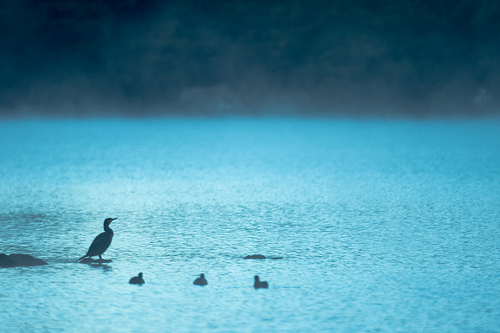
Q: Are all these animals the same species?
A: Yes, all the animals are ducks.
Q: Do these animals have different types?
A: No, all the animals are ducks.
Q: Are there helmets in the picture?
A: No, there are no helmets.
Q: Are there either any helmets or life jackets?
A: No, there are no helmets or life jackets.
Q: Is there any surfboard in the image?
A: No, there are no surfboards.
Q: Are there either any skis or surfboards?
A: No, there are no surfboards or skis.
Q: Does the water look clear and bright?
A: Yes, the water is clear and bright.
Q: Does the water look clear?
A: Yes, the water is clear.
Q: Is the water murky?
A: No, the water is clear.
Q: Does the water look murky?
A: No, the water is clear.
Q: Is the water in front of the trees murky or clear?
A: The water is clear.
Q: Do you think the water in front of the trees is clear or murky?
A: The water is clear.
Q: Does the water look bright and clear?
A: Yes, the water is bright and clear.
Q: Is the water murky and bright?
A: No, the water is bright but clear.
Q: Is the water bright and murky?
A: No, the water is bright but clear.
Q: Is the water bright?
A: Yes, the water is bright.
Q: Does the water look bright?
A: Yes, the water is bright.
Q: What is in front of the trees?
A: The water is in front of the trees.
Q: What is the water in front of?
A: The water is in front of the trees.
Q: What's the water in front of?
A: The water is in front of the trees.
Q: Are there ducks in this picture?
A: Yes, there is a duck.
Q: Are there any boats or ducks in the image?
A: Yes, there is a duck.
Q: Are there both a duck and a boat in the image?
A: No, there is a duck but no boats.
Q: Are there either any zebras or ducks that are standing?
A: Yes, the duck is standing.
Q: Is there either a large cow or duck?
A: Yes, there is a large duck.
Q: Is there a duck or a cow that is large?
A: Yes, the duck is large.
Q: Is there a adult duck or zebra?
A: Yes, there is an adult duck.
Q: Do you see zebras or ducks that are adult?
A: Yes, the duck is adult.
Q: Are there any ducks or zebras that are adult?
A: Yes, the duck is adult.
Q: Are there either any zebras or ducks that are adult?
A: Yes, the duck is adult.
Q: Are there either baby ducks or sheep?
A: Yes, there is a baby duck.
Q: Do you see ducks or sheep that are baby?
A: Yes, the duck is a baby.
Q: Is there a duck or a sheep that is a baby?
A: Yes, the duck is a baby.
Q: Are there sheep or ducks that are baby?
A: Yes, the duck is a baby.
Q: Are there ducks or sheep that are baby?
A: Yes, the duck is a baby.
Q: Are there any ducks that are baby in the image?
A: Yes, there is a baby duck.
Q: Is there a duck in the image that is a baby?
A: Yes, there is a duck that is a baby.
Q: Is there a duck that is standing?
A: Yes, there is a duck that is standing.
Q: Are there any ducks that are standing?
A: Yes, there is a duck that is standing.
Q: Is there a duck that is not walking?
A: Yes, there is a duck that is standing.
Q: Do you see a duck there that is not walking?
A: Yes, there is a duck that is standing .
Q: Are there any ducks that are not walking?
A: Yes, there is a duck that is standing.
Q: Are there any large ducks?
A: Yes, there is a large duck.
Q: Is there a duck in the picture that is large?
A: Yes, there is a duck that is large.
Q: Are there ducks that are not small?
A: Yes, there is a large duck.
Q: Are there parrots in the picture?
A: No, there are no parrots.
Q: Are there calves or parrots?
A: No, there are no parrots or calves.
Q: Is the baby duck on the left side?
A: Yes, the duck is on the left of the image.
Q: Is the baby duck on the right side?
A: No, the duck is on the left of the image.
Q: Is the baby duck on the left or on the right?
A: The duck is on the left of the image.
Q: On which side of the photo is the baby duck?
A: The duck is on the left of the image.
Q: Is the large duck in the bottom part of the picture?
A: Yes, the duck is in the bottom of the image.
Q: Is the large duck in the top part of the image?
A: No, the duck is in the bottom of the image.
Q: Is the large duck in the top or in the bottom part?
A: The duck is in the bottom of the image.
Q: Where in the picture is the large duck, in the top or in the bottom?
A: The duck is in the bottom of the image.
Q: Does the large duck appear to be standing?
A: Yes, the duck is standing.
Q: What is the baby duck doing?
A: The duck is standing.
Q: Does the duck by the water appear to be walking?
A: No, the duck is standing.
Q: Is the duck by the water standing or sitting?
A: The duck is standing.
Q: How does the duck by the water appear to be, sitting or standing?
A: The duck is standing.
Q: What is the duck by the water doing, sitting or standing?
A: The duck is standing.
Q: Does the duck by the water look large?
A: Yes, the duck is large.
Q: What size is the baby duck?
A: The duck is large.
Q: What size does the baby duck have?
A: The duck has large size.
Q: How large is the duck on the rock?
A: The duck is large.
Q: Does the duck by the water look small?
A: No, the duck is large.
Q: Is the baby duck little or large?
A: The duck is large.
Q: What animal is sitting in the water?
A: The duck is sitting in the water.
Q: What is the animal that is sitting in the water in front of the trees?
A: The animal is a duck.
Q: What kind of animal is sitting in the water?
A: The animal is a duck.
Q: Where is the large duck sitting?
A: The duck is sitting in the water.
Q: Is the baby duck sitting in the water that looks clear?
A: Yes, the duck is sitting in the water.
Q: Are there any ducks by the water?
A: Yes, there is a duck by the water.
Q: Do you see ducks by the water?
A: Yes, there is a duck by the water.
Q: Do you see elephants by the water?
A: No, there is a duck by the water.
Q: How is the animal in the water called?
A: The animal is a duck.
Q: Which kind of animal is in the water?
A: The animal is a duck.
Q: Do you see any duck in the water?
A: Yes, there is a duck in the water.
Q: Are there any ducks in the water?
A: Yes, there is a duck in the water.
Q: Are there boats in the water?
A: No, there is a duck in the water.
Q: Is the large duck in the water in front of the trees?
A: Yes, the duck is in the water.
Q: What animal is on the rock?
A: The duck is on the rock.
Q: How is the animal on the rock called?
A: The animal is a duck.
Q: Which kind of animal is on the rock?
A: The animal is a duck.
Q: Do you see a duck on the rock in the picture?
A: Yes, there is a duck on the rock.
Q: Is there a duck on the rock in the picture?
A: Yes, there is a duck on the rock.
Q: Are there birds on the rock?
A: No, there is a duck on the rock.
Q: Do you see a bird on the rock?
A: No, there is a duck on the rock.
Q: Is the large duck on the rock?
A: Yes, the duck is on the rock.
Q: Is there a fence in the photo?
A: No, there are no fences.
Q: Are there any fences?
A: No, there are no fences.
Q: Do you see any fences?
A: No, there are no fences.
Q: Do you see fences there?
A: No, there are no fences.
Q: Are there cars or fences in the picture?
A: No, there are no fences or cars.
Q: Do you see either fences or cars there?
A: No, there are no fences or cars.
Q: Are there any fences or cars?
A: No, there are no fences or cars.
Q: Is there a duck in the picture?
A: Yes, there are ducks.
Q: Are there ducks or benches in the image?
A: Yes, there are ducks.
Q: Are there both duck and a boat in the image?
A: No, there are ducks but no boats.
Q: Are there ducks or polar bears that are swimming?
A: Yes, the ducks are swimming.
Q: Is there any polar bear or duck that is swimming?
A: Yes, the ducks are swimming.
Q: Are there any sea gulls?
A: No, there are no sea gulls.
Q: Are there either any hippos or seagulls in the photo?
A: No, there are no seagulls or hippos.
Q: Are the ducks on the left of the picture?
A: Yes, the ducks are on the left of the image.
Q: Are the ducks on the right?
A: No, the ducks are on the left of the image.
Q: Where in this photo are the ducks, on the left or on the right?
A: The ducks are on the left of the image.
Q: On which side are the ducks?
A: The ducks are on the left of the image.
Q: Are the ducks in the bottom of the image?
A: Yes, the ducks are in the bottom of the image.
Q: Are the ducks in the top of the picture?
A: No, the ducks are in the bottom of the image.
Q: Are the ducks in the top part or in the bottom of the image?
A: The ducks are in the bottom of the image.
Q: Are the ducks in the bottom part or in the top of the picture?
A: The ducks are in the bottom of the image.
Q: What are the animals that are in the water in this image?
A: The animals are ducks.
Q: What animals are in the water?
A: The animals are ducks.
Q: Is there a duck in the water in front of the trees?
A: Yes, there are ducks in the water.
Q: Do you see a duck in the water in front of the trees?
A: Yes, there are ducks in the water.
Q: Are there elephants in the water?
A: No, there are ducks in the water.